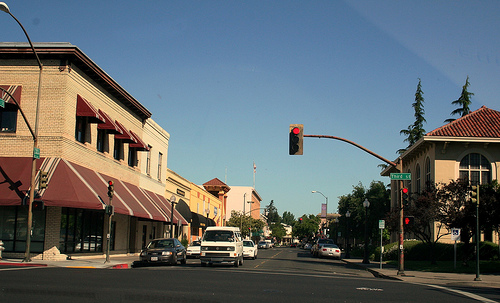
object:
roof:
[379, 105, 500, 178]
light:
[293, 126, 301, 133]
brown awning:
[0, 155, 188, 227]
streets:
[1, 248, 500, 303]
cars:
[200, 226, 246, 268]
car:
[240, 240, 259, 261]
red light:
[402, 188, 409, 192]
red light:
[300, 218, 304, 221]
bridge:
[308, 212, 354, 220]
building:
[0, 40, 496, 261]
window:
[455, 153, 495, 191]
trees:
[225, 181, 500, 265]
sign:
[452, 228, 462, 241]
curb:
[344, 259, 397, 281]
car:
[139, 239, 190, 267]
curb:
[0, 253, 145, 269]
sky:
[0, 0, 500, 222]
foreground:
[5, 204, 492, 296]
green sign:
[390, 173, 413, 181]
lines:
[255, 251, 284, 269]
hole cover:
[356, 286, 383, 292]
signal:
[404, 216, 413, 225]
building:
[2, 39, 138, 256]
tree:
[375, 80, 428, 171]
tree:
[446, 70, 474, 121]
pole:
[301, 134, 406, 274]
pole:
[394, 154, 403, 275]